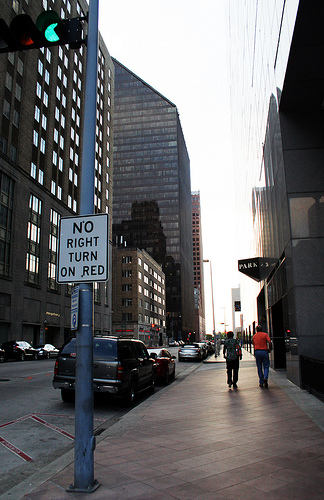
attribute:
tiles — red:
[101, 437, 323, 499]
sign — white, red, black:
[57, 214, 108, 284]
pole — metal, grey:
[67, 0, 99, 492]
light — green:
[44, 21, 63, 43]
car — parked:
[52, 336, 156, 406]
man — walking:
[253, 325, 272, 388]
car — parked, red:
[146, 347, 175, 386]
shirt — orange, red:
[252, 331, 270, 352]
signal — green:
[0, 13, 88, 54]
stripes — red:
[0, 414, 76, 463]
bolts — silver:
[67, 15, 81, 44]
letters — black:
[62, 221, 104, 277]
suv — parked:
[52, 333, 159, 405]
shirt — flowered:
[223, 337, 242, 362]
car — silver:
[179, 343, 207, 362]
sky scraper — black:
[112, 56, 196, 341]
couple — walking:
[223, 324, 272, 390]